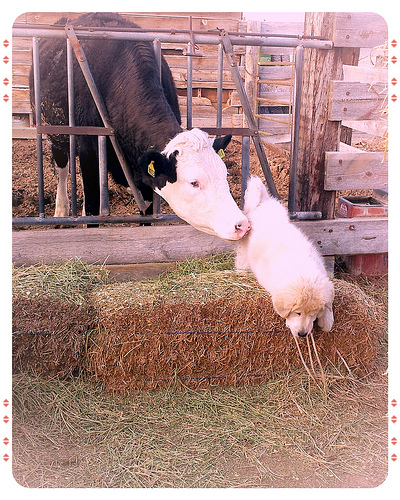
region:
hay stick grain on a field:
[75, 411, 102, 441]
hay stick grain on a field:
[132, 400, 156, 428]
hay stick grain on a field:
[122, 433, 174, 464]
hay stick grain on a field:
[73, 431, 107, 458]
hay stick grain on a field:
[229, 392, 256, 419]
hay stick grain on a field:
[201, 429, 245, 462]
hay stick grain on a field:
[253, 441, 283, 454]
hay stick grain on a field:
[276, 396, 310, 418]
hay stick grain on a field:
[313, 421, 349, 443]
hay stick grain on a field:
[309, 449, 351, 467]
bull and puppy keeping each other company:
[25, 12, 353, 340]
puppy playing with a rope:
[268, 260, 337, 405]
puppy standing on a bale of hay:
[84, 161, 388, 382]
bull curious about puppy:
[128, 120, 340, 346]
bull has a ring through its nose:
[224, 210, 255, 241]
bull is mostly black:
[26, 12, 255, 244]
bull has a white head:
[130, 119, 258, 245]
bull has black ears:
[132, 123, 252, 244]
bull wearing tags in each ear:
[126, 120, 242, 189]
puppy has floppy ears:
[263, 269, 344, 345]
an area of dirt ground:
[12, 386, 388, 487]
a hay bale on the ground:
[85, 270, 384, 393]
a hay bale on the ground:
[12, 256, 109, 379]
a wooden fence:
[12, 11, 388, 283]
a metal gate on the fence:
[11, 21, 332, 225]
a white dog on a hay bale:
[235, 172, 334, 337]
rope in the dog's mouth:
[293, 331, 323, 384]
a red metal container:
[337, 195, 387, 278]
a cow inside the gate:
[28, 11, 250, 241]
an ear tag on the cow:
[147, 159, 155, 178]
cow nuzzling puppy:
[27, 14, 339, 342]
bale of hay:
[92, 268, 383, 400]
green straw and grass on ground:
[10, 380, 374, 492]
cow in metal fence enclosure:
[26, 10, 251, 246]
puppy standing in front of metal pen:
[228, 173, 337, 342]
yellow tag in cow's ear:
[142, 153, 158, 183]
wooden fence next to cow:
[290, 13, 391, 252]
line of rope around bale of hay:
[106, 325, 282, 340]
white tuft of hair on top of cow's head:
[159, 118, 213, 163]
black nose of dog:
[294, 327, 309, 341]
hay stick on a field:
[57, 404, 79, 426]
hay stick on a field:
[80, 414, 132, 464]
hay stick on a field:
[153, 409, 189, 446]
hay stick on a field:
[173, 459, 201, 483]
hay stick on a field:
[230, 383, 257, 424]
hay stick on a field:
[246, 451, 263, 468]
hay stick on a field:
[275, 430, 314, 491]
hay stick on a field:
[275, 368, 314, 428]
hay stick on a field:
[313, 404, 358, 464]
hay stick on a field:
[344, 401, 378, 414]